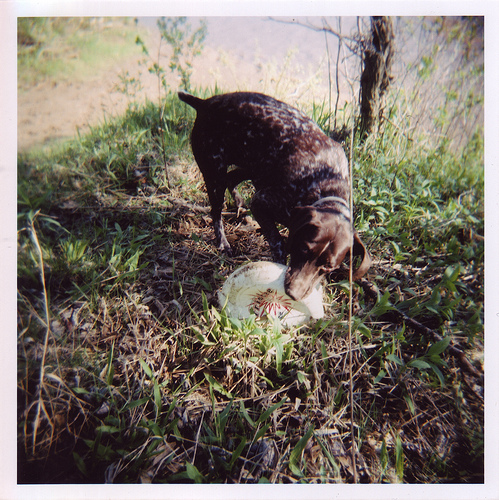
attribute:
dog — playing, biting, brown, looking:
[206, 103, 383, 235]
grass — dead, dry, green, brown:
[397, 235, 446, 336]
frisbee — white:
[245, 267, 296, 311]